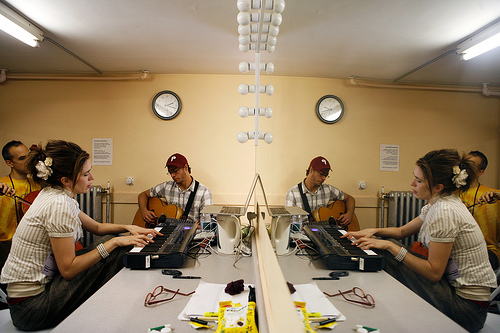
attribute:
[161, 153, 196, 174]
cap — maroon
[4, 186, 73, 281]
blouse — stripes